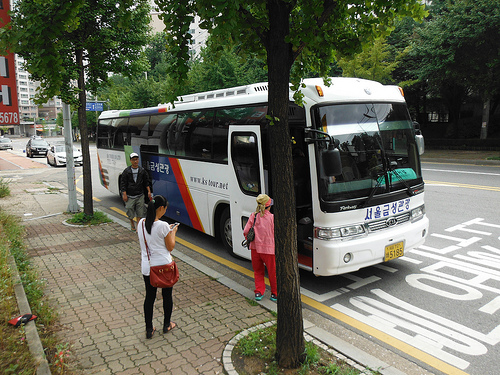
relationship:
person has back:
[136, 192, 180, 339] [137, 217, 163, 264]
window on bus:
[173, 108, 214, 160] [94, 77, 431, 282]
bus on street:
[94, 77, 431, 282] [3, 134, 497, 374]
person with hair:
[136, 192, 180, 339] [141, 197, 159, 241]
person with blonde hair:
[241, 192, 288, 301] [252, 188, 270, 215]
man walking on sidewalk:
[77, 137, 185, 221] [16, 227, 211, 364]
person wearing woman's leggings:
[136, 192, 180, 339] [144, 273, 173, 333]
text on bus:
[186, 174, 229, 190] [94, 77, 478, 308]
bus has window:
[94, 77, 431, 282] [156, 111, 233, 167]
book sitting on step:
[8, 309, 40, 334] [0, 224, 54, 373]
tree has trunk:
[191, 0, 426, 374] [263, 7, 308, 370]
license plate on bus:
[375, 239, 407, 267] [94, 77, 431, 282]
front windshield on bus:
[317, 113, 416, 188] [94, 77, 431, 282]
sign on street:
[65, 106, 145, 148] [3, 134, 497, 374]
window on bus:
[98, 118, 113, 147] [94, 77, 431, 282]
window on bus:
[95, 114, 178, 157] [94, 75, 434, 277]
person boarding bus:
[233, 181, 290, 305] [67, 63, 437, 310]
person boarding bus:
[125, 191, 197, 343] [67, 63, 437, 310]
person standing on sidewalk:
[136, 192, 180, 339] [0, 173, 410, 373]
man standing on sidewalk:
[118, 151, 155, 234] [0, 173, 410, 373]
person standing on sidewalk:
[241, 192, 288, 301] [0, 173, 410, 373]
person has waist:
[136, 192, 180, 339] [142, 246, 176, 263]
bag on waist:
[146, 267, 181, 290] [142, 246, 176, 263]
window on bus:
[127, 116, 150, 149] [94, 77, 431, 282]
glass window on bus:
[148, 104, 185, 154] [73, 74, 445, 291]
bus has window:
[94, 75, 434, 277] [229, 127, 263, 196]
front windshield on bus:
[315, 98, 425, 203] [94, 77, 431, 282]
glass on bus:
[198, 90, 291, 145] [30, 48, 472, 285]